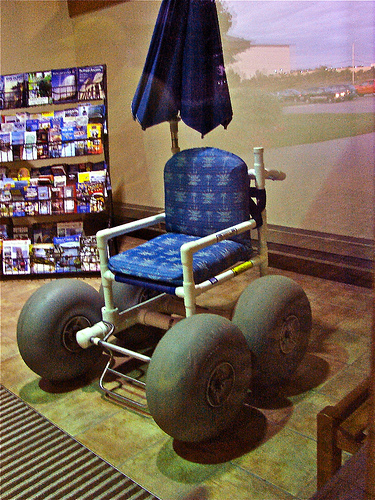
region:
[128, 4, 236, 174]
closed umbrella over chair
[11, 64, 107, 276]
pamphlets on rack shelves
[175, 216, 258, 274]
white arm rest on chair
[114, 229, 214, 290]
cushion on chair seat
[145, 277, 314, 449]
two giant wheels on chair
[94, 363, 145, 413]
metal bars on chair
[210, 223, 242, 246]
label on white bar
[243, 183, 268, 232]
straps on back of chair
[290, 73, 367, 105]
cars parked in lot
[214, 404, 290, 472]
shadow of wheel on floor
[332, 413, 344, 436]
the chair is wooden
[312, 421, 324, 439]
the chair is wooden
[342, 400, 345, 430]
the chair is wooden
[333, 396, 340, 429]
the chair is wooden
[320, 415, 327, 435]
the chair is wooden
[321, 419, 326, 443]
the chair is wooden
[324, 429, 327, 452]
the chair is wooden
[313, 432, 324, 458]
the chair is wooden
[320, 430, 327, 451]
the chair is wooden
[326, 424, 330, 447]
the chair is wooden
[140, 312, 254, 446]
Balloon tires on a chair made of PVC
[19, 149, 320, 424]
Mobile chair made of PVC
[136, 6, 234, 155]
Umbrella attached to mobile chair made of PVC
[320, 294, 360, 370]
Tile covered floor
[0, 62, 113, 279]
Brochure rack for tourist attractions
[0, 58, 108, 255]
Brochures for tourist attractions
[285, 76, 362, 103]
Cars parked in the parking lot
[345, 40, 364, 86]
Utility pole supporting wires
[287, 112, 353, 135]
Patch of grass outside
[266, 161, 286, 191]
Handle for pushing mobile chair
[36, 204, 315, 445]
very large thick tires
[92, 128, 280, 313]
light and dark blue patterned seat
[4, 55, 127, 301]
large shelf of brochures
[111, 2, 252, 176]
dark blue umbrella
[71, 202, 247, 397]
chair made of plumbing tubes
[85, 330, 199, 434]
small silver foot rest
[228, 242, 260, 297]
small yellow label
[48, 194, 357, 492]
colorful tiled floor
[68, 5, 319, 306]
chair with umbrella attached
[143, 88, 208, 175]
umbrella pole attached to the chair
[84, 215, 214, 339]
chair frame made out of PVC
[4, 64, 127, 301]
magazine rack with four shelves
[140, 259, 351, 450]
bigg round beach tires attached to chair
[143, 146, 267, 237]
blue cushion back on chair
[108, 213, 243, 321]
blue seat cushion with design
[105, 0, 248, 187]
blue umbrella attached to back of chair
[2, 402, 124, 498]
brown striped area rug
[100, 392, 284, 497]
brown tile flooring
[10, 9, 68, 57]
cream color painted walls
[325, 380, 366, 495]
edge of wooden table and chair